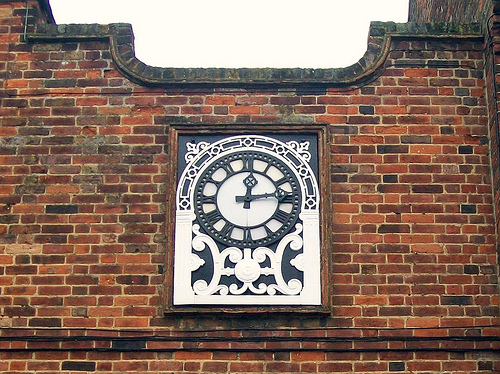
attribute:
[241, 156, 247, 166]
number — blue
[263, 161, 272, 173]
number — blue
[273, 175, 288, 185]
number — blue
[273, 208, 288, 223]
number — blue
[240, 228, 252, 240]
number — blue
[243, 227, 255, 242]
numeral six — black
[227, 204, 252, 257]
edge — clock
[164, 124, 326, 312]
clock — blue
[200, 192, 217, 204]
nine — black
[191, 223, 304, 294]
scroll — decorative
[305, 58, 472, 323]
wall — red, brown, Brick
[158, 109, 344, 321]
clock — framed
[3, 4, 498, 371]
wall — brick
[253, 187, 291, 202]
hand — long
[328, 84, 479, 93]
bricks — dark